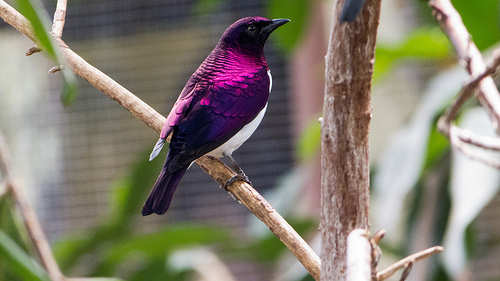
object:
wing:
[146, 73, 202, 163]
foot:
[219, 169, 255, 194]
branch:
[0, 0, 324, 280]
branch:
[428, 0, 499, 131]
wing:
[196, 67, 266, 120]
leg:
[211, 150, 244, 175]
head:
[216, 14, 290, 48]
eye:
[246, 24, 256, 32]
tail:
[140, 153, 189, 218]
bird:
[139, 15, 291, 218]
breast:
[208, 67, 271, 102]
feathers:
[210, 73, 246, 93]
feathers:
[152, 169, 181, 217]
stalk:
[313, 0, 382, 280]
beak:
[261, 18, 292, 37]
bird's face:
[222, 15, 296, 50]